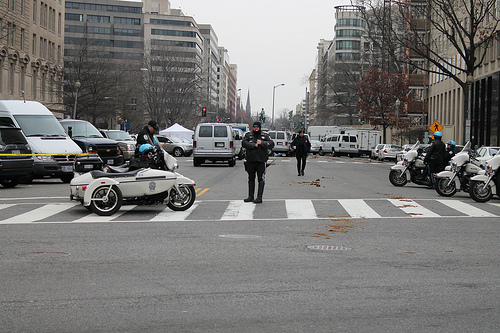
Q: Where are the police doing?
A: Checking the street.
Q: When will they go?
A: Later.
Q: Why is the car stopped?
A: Police are patrolling traffic.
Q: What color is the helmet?
A: Blue.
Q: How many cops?
A: 6.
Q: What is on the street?
A: Van,cars,motorbikes.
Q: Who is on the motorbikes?
A: The cops.